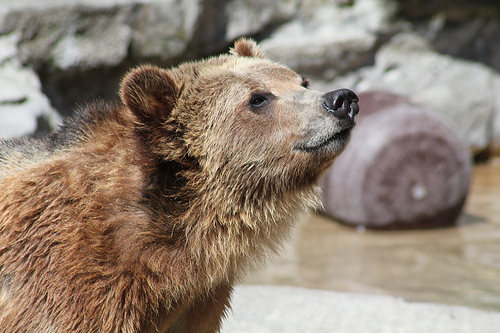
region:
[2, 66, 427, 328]
Brown bear is curious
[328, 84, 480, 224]
Purple barrel in background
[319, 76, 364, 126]
Bear's nose is black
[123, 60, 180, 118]
Right ear is short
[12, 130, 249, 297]
Hair is prickly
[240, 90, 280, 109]
Eye is small and black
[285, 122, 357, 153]
Muzzle is short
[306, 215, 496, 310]
Muddy water in background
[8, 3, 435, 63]
Rocks behind bear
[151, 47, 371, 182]
Face of animal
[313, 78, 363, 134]
The bear has a large black nose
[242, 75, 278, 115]
Bear has dark brown eyes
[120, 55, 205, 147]
Bear has small furry ears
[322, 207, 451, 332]
Clear water in the background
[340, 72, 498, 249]
Bucket is laying on its side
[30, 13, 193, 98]
Large rocks in the background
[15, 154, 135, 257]
The bear has short hair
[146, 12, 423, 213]
The bear is sniffing the air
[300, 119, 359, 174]
Bears mouth is closed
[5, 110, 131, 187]
bear has some black hair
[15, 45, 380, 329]
a bear at the zoo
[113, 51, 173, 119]
ear on the bear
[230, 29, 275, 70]
ear on the bear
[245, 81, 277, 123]
eye on the bear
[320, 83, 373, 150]
nose on the bear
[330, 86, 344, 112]
nostril on the nose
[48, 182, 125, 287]
fur on the bear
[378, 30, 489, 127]
rock in the background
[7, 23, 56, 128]
rock in the background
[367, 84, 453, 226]
barrel in the water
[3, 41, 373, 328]
The bear is brown.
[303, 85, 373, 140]
The nose is black.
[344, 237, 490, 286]
The water is brown.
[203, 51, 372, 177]
The bear is looking up.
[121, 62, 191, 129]
The ears are small.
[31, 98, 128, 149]
Black on the back.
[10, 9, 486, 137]
Rocks in the background.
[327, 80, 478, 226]
Barrel in the water.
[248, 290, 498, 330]
The beach is white.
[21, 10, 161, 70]
The rock is grey.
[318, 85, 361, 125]
the bear's nose is black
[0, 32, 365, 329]
the bear is fluffy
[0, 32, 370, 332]
the bear is brown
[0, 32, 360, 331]
the bear is fuzzy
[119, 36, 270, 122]
the bear has round ears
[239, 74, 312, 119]
the bear has black eyes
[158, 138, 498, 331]
the ground is brown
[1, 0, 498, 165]
the boulders are grey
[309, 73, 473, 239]
the stone is brown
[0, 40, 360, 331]
the bear is sniffing the air